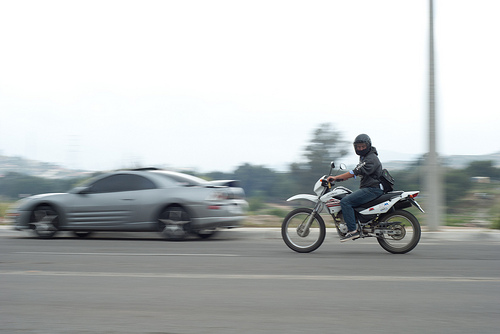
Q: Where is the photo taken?
A: Road.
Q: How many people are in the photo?
A: One.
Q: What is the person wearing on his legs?
A: Pants.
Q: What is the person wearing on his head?
A: Helmet.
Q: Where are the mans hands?
A: Handlebars.